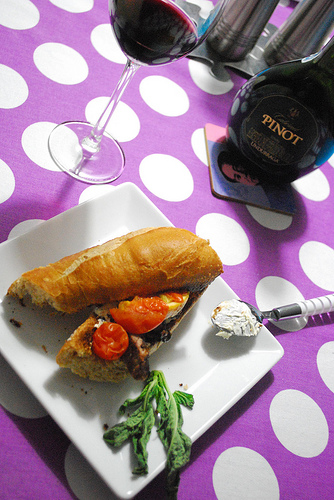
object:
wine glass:
[46, 0, 230, 185]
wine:
[108, 0, 198, 67]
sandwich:
[8, 222, 224, 384]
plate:
[1, 181, 285, 500]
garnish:
[104, 367, 195, 476]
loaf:
[5, 225, 223, 317]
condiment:
[210, 295, 261, 341]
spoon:
[211, 292, 334, 341]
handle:
[295, 291, 334, 317]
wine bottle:
[226, 33, 334, 192]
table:
[1, 0, 333, 498]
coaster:
[202, 120, 295, 215]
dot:
[137, 151, 196, 206]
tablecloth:
[0, 0, 333, 499]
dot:
[193, 210, 250, 267]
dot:
[31, 40, 91, 86]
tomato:
[92, 321, 129, 362]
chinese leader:
[216, 147, 279, 192]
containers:
[207, 0, 278, 62]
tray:
[184, 0, 282, 83]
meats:
[91, 305, 151, 382]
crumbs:
[39, 341, 49, 356]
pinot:
[261, 113, 303, 147]